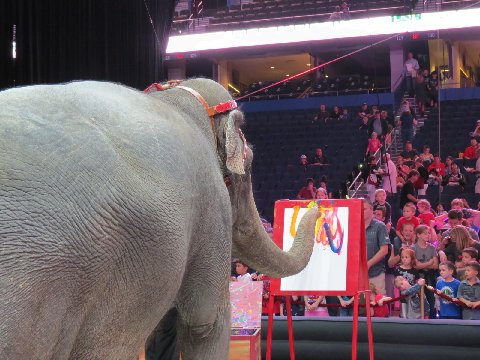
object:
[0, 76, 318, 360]
elephant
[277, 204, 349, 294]
paper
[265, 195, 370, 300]
easel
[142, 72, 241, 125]
harness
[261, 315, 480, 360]
fence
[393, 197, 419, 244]
spectators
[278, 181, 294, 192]
seats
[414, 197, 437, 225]
kids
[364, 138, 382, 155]
shirt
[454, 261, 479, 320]
boy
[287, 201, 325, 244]
paint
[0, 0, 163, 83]
curtain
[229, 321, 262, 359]
box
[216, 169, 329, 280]
trunks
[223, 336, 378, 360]
stage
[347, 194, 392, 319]
adults